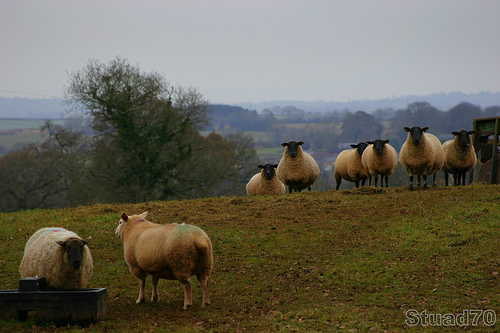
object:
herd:
[245, 125, 480, 197]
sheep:
[19, 226, 94, 289]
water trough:
[1, 282, 108, 323]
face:
[63, 238, 87, 269]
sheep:
[274, 140, 320, 194]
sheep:
[398, 124, 446, 190]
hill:
[0, 184, 499, 333]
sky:
[0, 1, 500, 104]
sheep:
[113, 208, 216, 309]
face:
[115, 214, 126, 237]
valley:
[0, 90, 499, 214]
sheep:
[441, 129, 477, 187]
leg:
[444, 171, 449, 187]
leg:
[452, 173, 458, 186]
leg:
[461, 172, 466, 186]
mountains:
[451, 89, 499, 120]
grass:
[1, 182, 500, 332]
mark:
[176, 223, 191, 236]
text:
[404, 307, 496, 327]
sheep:
[333, 141, 369, 191]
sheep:
[360, 139, 398, 188]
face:
[287, 140, 299, 157]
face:
[410, 126, 423, 143]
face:
[458, 129, 471, 149]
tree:
[66, 57, 210, 202]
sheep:
[245, 163, 286, 198]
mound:
[342, 186, 386, 195]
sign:
[466, 116, 499, 182]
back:
[143, 223, 203, 241]